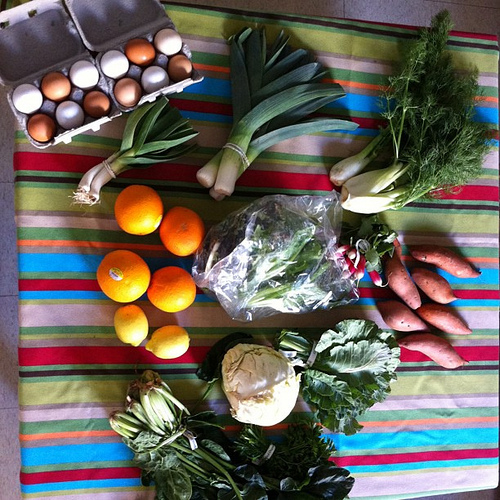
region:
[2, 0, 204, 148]
A carton with dozen eggs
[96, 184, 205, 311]
Four oranges sitting on a table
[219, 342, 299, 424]
A cabbage sitting on the table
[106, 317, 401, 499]
A group of green leafy vegetables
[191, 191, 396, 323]
A vegetable inside a plastic bag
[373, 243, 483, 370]
Six red sweet potatoes sitting on a table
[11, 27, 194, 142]
Twelve eggs of different colors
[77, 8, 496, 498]
A wide variety of produce lying together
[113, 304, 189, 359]
Two lemons sitting on a table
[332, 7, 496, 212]
A bunch of fennel lying on a table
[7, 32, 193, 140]
brown and white eggs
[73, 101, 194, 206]
green onions on table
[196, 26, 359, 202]
bunches of leaks on table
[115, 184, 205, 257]
two oranges on table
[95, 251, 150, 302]
grapefruit sitting on table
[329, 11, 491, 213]
fennel bunches on table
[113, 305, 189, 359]
two lemons on table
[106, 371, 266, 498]
greens bunches on table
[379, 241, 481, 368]
swet potatoes on table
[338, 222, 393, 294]
red radishes on table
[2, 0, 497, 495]
bright striped fabric over gray tiled surface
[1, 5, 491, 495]
produce and dairy displayed on cloth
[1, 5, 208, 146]
brown and white eggs in paper container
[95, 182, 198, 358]
four oranges over two lemons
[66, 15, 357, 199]
tied stalks of two leeks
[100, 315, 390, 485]
round head of lettuce between leafy green vegetables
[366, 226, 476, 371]
long brown ovals of sweet potatos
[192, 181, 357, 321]
greens inside plastic bag reflecting light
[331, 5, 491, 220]
dark green ferns above white bulbs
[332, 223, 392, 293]
small red and white radishes with leaves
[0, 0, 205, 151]
Box containing both white and brown eggs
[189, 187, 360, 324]
Greens inside a plastic bag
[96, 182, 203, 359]
Citrus fruits on the table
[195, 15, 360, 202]
Three leaks bundled together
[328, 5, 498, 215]
Three fennel bulbs with leafy tops still on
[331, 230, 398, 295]
A bunch of radishes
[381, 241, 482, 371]
Six sweet potatoes on the table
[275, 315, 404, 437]
A bunch of some kind of leafy green vegetable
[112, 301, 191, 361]
Two lemons placed on the table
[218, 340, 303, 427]
A whole head of cabbage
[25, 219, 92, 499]
Tablecloth with multiple colored stripes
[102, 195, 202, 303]
Four oranges on table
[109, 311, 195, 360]
Two lemons on table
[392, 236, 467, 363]
Six sweet potatoes on table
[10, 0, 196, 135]
Crate of dozen eggs on table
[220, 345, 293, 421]
Head of cabbage on table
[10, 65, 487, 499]
Multiple produce on table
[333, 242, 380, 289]
Bunch of radishes on table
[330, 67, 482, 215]
Bok choy on table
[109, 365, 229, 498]
Bunch of greens on table